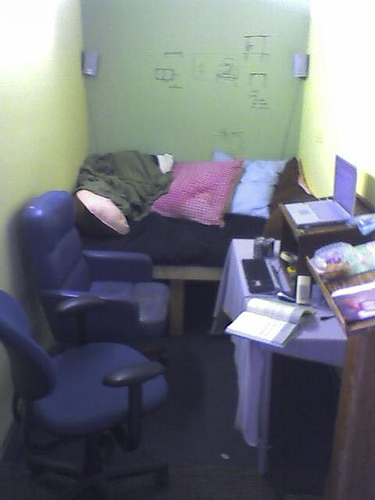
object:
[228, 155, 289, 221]
blue pillow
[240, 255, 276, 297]
keyboard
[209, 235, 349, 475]
table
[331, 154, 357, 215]
screen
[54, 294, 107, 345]
armrests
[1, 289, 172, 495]
chair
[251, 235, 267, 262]
cans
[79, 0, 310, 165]
wall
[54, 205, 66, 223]
blue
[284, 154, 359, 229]
laptop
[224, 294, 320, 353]
book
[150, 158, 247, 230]
pillow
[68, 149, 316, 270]
bed